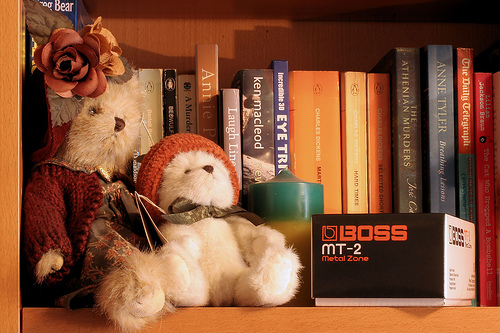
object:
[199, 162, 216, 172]
nose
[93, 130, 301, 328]
bear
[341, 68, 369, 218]
book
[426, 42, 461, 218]
book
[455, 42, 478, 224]
book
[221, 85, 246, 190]
book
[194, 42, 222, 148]
book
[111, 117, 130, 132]
nose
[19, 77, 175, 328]
bear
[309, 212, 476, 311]
box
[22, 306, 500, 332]
shelf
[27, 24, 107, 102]
rose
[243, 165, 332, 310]
candle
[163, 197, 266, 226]
bow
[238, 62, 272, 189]
book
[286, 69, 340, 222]
book arranged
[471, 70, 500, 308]
book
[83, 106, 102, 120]
eye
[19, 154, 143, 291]
sweater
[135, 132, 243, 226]
hat